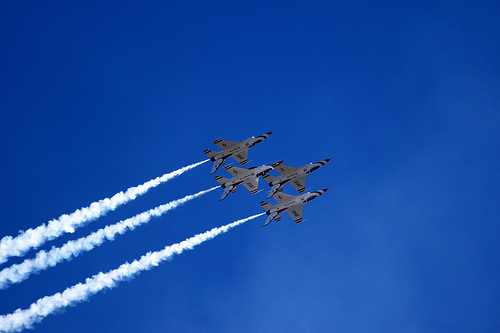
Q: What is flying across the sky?
A: Jet planes.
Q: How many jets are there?
A: 4.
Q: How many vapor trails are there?
A: 3.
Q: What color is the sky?
A: Blue.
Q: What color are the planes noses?
A: Black.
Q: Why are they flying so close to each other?
A: They are a stunt team.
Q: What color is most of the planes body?
A: Grey.